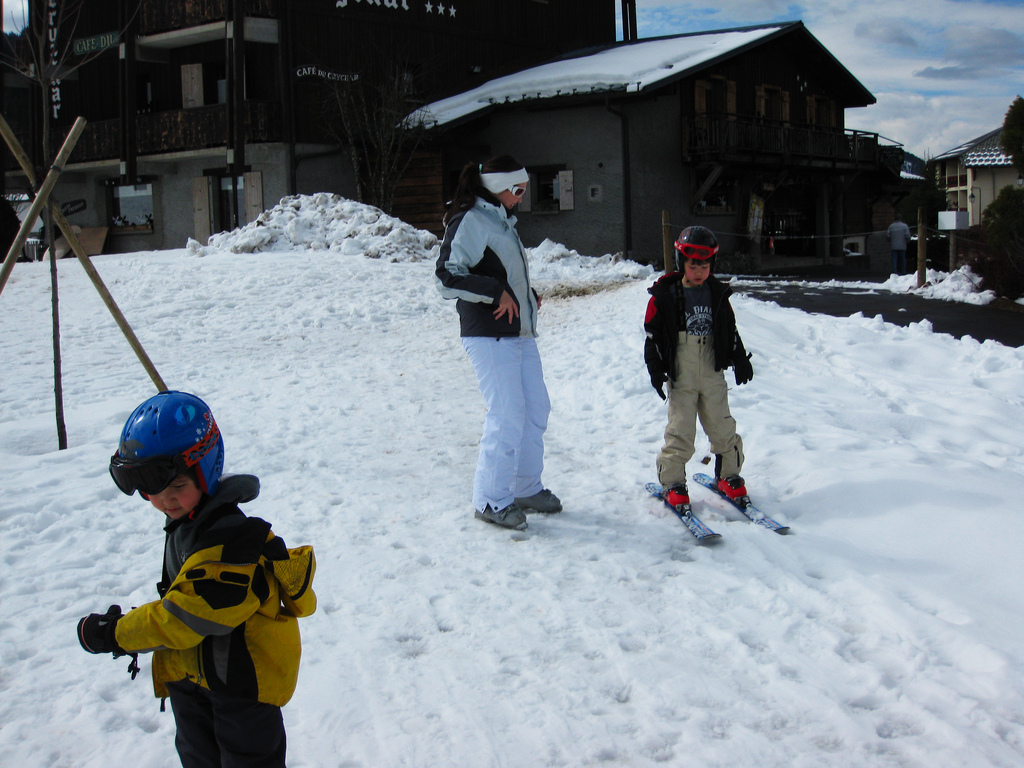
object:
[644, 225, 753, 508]
person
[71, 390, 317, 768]
person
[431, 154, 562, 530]
person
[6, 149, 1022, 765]
snow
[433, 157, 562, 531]
woman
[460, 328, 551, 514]
pants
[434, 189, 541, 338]
coat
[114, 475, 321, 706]
child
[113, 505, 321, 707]
coat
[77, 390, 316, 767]
child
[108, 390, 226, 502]
helmet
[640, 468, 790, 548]
skis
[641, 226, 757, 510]
child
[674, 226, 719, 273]
helmet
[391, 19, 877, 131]
roof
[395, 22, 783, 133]
snow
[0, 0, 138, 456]
sapling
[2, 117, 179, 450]
poles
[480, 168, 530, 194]
headband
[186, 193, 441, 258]
pile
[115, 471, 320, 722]
jacket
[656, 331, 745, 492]
pants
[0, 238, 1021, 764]
prints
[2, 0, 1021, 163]
sky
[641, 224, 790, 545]
child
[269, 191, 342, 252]
snow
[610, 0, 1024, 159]
cloud